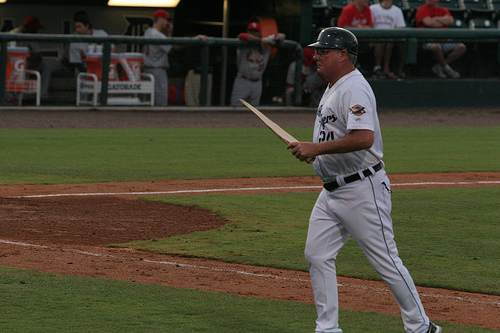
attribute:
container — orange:
[4, 44, 30, 92]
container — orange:
[84, 52, 118, 83]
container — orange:
[120, 52, 148, 89]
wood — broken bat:
[237, 96, 315, 164]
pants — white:
[305, 160, 431, 332]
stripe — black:
[367, 174, 427, 321]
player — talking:
[68, 13, 116, 80]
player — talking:
[4, 14, 54, 103]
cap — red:
[152, 8, 171, 20]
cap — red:
[23, 14, 45, 31]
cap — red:
[247, 19, 261, 30]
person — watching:
[337, 0, 386, 81]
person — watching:
[369, 0, 409, 82]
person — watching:
[415, 0, 466, 81]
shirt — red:
[416, 5, 452, 30]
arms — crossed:
[423, 15, 454, 25]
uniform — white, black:
[301, 69, 431, 331]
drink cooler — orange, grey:
[6, 43, 32, 91]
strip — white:
[82, 180, 332, 194]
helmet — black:
[292, 10, 383, 67]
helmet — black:
[305, 25, 360, 54]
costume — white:
[298, 68, 426, 331]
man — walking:
[283, 25, 443, 332]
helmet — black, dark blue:
[307, 26, 361, 58]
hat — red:
[147, 6, 174, 21]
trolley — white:
[74, 65, 156, 107]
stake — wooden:
[234, 100, 301, 146]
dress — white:
[301, 67, 433, 332]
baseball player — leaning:
[281, 21, 431, 330]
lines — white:
[0, 230, 495, 322]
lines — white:
[1, 173, 499, 205]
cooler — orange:
[86, 53, 114, 83]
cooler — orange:
[118, 50, 145, 78]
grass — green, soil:
[4, 112, 498, 330]